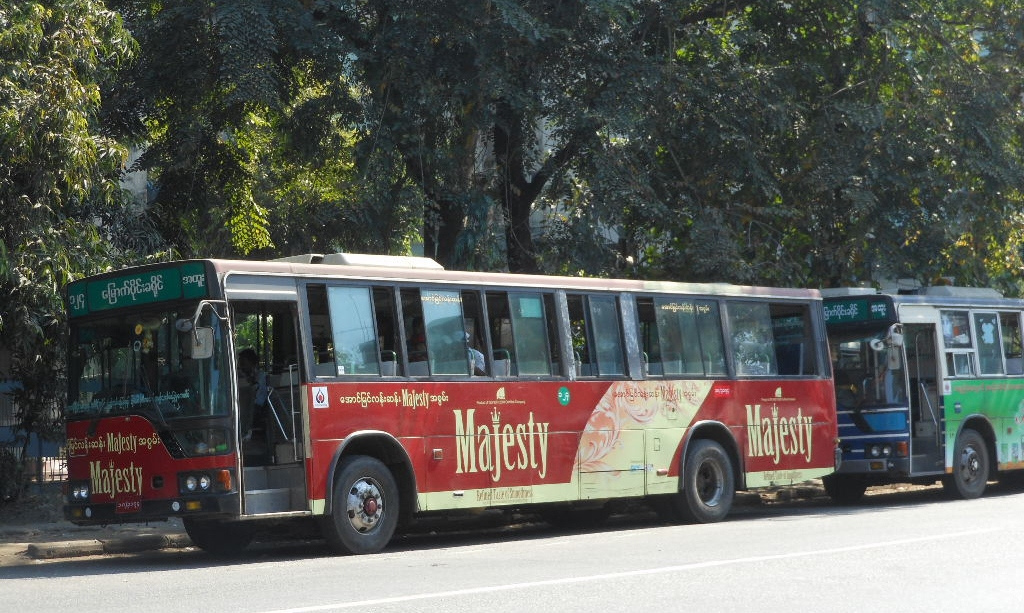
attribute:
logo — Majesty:
[442, 405, 561, 486]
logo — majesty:
[434, 406, 566, 493]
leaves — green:
[48, 24, 131, 66]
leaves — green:
[361, 22, 413, 92]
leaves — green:
[571, 20, 634, 87]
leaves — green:
[828, 81, 913, 170]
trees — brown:
[3, 5, 137, 403]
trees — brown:
[295, 5, 494, 263]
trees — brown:
[489, 7, 671, 273]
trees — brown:
[787, 5, 997, 282]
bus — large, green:
[824, 288, 1019, 503]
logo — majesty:
[448, 403, 555, 475]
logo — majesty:
[450, 405, 565, 485]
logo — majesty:
[453, 403, 547, 481]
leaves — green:
[789, 7, 906, 85]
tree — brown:
[649, 0, 917, 251]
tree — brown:
[623, 102, 812, 269]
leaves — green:
[673, 173, 760, 247]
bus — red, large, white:
[57, 245, 840, 555]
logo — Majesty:
[450, 410, 554, 482]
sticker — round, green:
[550, 384, 576, 404]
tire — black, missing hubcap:
[681, 435, 740, 526]